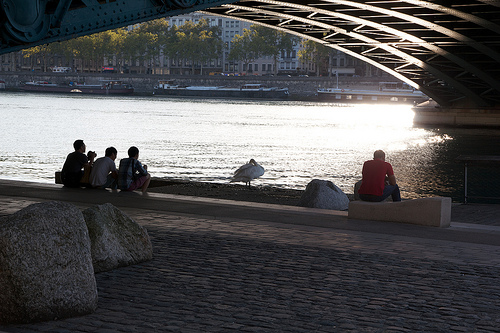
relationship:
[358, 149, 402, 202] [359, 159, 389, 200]
man in shirt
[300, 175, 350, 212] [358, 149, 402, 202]
rock near man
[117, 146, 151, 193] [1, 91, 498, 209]
boy sitting near water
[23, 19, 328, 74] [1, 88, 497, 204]
trees on far side of river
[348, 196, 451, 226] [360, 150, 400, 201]
block with man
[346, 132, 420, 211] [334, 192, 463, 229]
man sitting on block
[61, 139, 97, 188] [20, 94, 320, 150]
boy sitting by water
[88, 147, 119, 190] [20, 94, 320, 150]
boy sitting by water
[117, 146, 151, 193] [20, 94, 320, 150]
boy sitting by water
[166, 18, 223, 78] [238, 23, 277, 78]
tree by building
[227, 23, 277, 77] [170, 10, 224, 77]
tree by building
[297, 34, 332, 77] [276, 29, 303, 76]
tree by building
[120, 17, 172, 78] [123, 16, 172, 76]
tree by building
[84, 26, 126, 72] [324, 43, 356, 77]
tree by building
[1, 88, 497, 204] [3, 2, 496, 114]
river beneath bridge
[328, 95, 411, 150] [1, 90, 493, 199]
sunlight reflecting off water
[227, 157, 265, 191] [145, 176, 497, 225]
bird on edge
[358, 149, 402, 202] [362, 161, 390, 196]
man has on shirt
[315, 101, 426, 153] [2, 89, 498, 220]
reflection on water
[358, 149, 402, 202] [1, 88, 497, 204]
man sits in front of river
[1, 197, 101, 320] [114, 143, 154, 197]
rock behind boy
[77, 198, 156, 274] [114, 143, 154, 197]
rock behind boy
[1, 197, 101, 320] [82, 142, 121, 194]
rock behind boy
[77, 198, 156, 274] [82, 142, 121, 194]
rock behind boy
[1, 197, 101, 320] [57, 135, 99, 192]
rock behind boy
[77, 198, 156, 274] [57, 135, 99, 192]
rock behind boy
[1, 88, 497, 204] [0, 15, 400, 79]
river in front of building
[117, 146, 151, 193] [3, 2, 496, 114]
boy are under a bridge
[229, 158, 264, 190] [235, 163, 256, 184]
bird touching h back